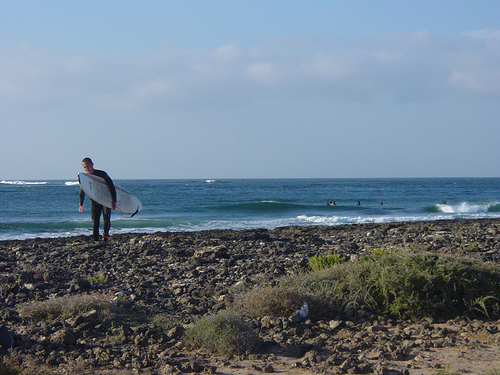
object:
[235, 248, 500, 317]
vegetation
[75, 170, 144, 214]
surfboard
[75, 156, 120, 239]
man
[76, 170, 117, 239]
wetsuit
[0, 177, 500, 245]
ocean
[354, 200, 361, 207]
person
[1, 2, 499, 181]
sky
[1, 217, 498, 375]
ground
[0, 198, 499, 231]
wave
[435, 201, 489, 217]
white spray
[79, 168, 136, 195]
strip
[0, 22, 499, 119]
cloud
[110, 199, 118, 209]
hand